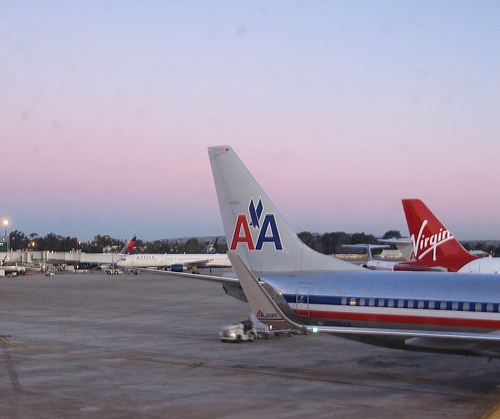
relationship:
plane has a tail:
[126, 146, 498, 372] [135, 138, 313, 337]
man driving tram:
[241, 317, 250, 332] [218, 311, 261, 346]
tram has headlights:
[218, 311, 261, 346] [216, 330, 238, 339]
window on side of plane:
[339, 296, 346, 308] [126, 146, 498, 372]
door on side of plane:
[293, 283, 312, 316] [126, 146, 498, 372]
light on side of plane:
[309, 327, 321, 334] [126, 146, 498, 372]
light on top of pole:
[2, 217, 11, 229] [1, 217, 14, 252]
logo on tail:
[226, 197, 291, 255] [135, 138, 313, 337]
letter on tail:
[225, 212, 257, 251] [135, 138, 313, 337]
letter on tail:
[254, 213, 284, 252] [135, 138, 313, 337]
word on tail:
[405, 220, 457, 264] [401, 197, 471, 273]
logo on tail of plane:
[226, 197, 291, 255] [126, 146, 498, 372]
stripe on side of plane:
[284, 292, 499, 315] [126, 146, 498, 372]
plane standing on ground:
[126, 146, 498, 372] [1, 271, 498, 418]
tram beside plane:
[218, 311, 261, 346] [126, 146, 498, 372]